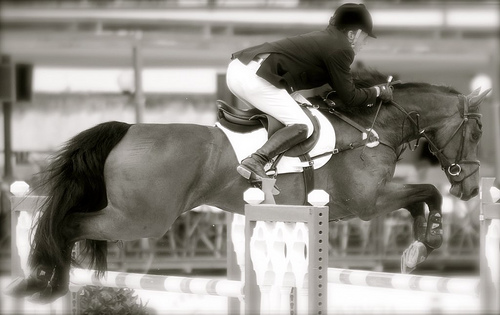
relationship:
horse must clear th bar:
[20, 82, 480, 256] [48, 250, 249, 313]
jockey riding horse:
[225, 2, 393, 197] [5, 82, 493, 295]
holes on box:
[312, 207, 325, 312] [239, 196, 328, 309]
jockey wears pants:
[225, 2, 393, 197] [223, 50, 318, 141]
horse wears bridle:
[5, 82, 493, 295] [423, 80, 492, 201]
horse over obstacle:
[5, 82, 493, 295] [3, 180, 490, 313]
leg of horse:
[367, 181, 448, 245] [5, 82, 493, 295]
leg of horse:
[402, 200, 428, 274] [5, 82, 493, 295]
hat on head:
[329, 4, 379, 38] [327, 2, 368, 53]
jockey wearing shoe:
[225, 2, 393, 197] [235, 159, 281, 193]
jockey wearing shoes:
[225, 2, 393, 197] [222, 120, 329, 157]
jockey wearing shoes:
[225, 2, 393, 197] [239, 122, 307, 181]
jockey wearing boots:
[225, 2, 393, 197] [232, 120, 313, 182]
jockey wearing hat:
[225, 2, 393, 197] [329, 1, 376, 38]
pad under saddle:
[215, 87, 337, 177] [219, 102, 336, 172]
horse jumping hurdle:
[5, 82, 493, 295] [6, 180, 330, 315]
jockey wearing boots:
[225, 2, 393, 197] [229, 122, 309, 182]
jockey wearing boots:
[225, 2, 393, 197] [238, 119, 317, 182]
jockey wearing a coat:
[225, 2, 393, 197] [231, 25, 379, 106]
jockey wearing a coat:
[225, 2, 393, 197] [231, 28, 376, 113]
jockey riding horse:
[196, 0, 401, 212] [5, 82, 493, 295]